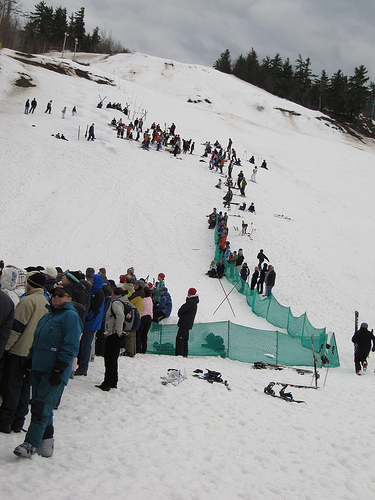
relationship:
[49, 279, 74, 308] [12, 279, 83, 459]
head of person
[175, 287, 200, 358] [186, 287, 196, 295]
person wearing head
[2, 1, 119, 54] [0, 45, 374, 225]
trees on hill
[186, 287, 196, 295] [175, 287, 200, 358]
head of person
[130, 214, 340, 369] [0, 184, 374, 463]
fence near spectators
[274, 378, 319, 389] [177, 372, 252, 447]
skis in snow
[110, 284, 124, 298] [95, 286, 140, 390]
head on person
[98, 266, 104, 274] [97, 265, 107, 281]
head on person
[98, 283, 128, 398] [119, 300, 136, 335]
woman wearing a backpack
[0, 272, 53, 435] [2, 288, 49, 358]
person wearing a coat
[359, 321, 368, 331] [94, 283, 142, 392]
head of a person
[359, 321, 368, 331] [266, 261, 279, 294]
head of a person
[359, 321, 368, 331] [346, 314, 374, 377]
head of a person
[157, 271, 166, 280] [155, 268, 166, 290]
head of a person